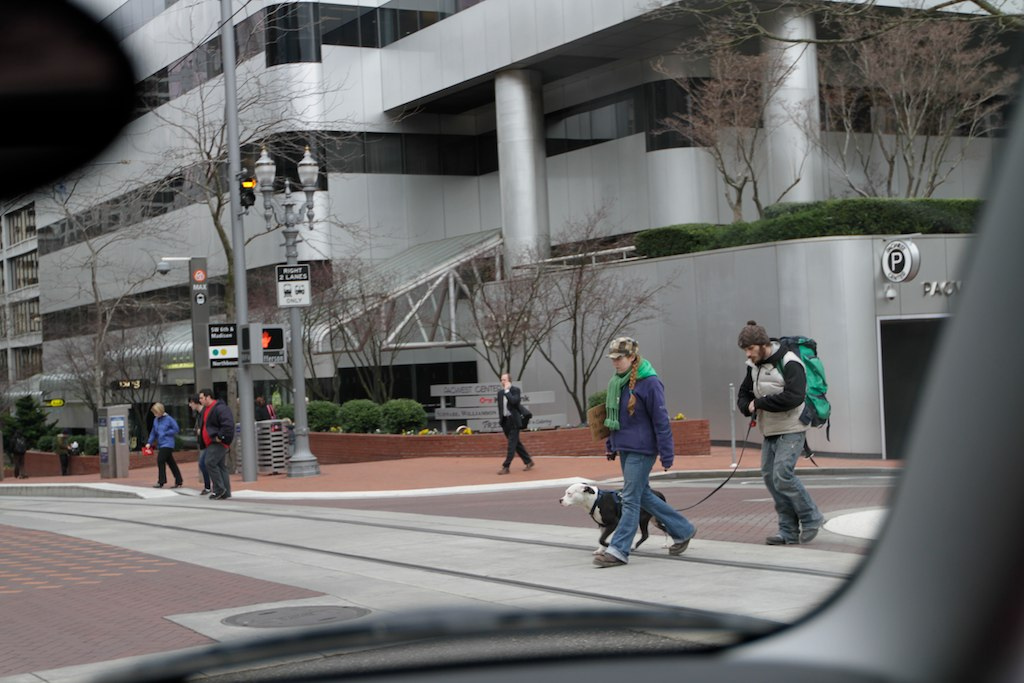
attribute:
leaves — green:
[417, 396, 431, 410]